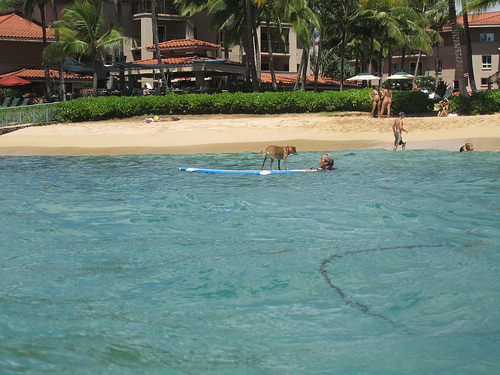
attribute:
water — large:
[1, 155, 498, 372]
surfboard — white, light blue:
[176, 165, 321, 173]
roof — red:
[429, 9, 496, 29]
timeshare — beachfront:
[0, 0, 496, 98]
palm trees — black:
[109, 2, 347, 102]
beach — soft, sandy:
[82, 94, 486, 149]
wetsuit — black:
[440, 104, 447, 113]